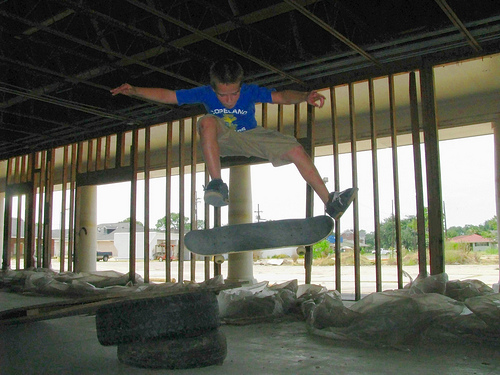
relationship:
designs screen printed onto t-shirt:
[217, 111, 251, 133] [171, 80, 278, 132]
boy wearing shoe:
[106, 57, 358, 223] [202, 180, 228, 205]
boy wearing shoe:
[106, 57, 358, 223] [325, 186, 357, 217]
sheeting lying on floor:
[5, 265, 499, 357] [1, 286, 497, 373]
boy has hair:
[106, 57, 358, 223] [202, 52, 274, 99]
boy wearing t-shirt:
[106, 57, 358, 223] [173, 81, 273, 133]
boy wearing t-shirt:
[106, 57, 358, 223] [166, 77, 273, 132]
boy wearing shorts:
[106, 57, 358, 223] [194, 114, 300, 166]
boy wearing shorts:
[106, 57, 358, 223] [197, 113, 302, 172]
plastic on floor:
[235, 274, 498, 354] [17, 279, 454, 374]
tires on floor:
[114, 329, 232, 372] [1, 286, 497, 373]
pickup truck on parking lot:
[92, 249, 114, 264] [11, 257, 498, 307]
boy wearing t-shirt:
[106, 57, 358, 223] [173, 81, 277, 128]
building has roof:
[443, 228, 498, 255] [442, 215, 498, 265]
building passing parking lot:
[443, 228, 498, 255] [4, 253, 497, 295]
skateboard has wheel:
[183, 215, 336, 263] [212, 252, 224, 263]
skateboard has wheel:
[183, 215, 336, 263] [295, 247, 306, 256]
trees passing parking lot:
[372, 207, 444, 257] [5, 255, 499, 300]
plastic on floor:
[218, 270, 498, 355] [1, 286, 497, 373]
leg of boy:
[198, 114, 225, 207] [106, 57, 358, 223]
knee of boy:
[195, 115, 215, 137] [106, 57, 358, 223]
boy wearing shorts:
[106, 57, 358, 223] [187, 107, 292, 153]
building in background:
[443, 228, 498, 255] [3, 193, 498, 268]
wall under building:
[384, 74, 404, 297] [2, 5, 500, 304]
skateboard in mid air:
[183, 215, 336, 263] [133, 174, 372, 274]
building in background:
[443, 228, 498, 255] [57, 70, 473, 303]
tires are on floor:
[99, 301, 232, 372] [37, 330, 95, 355]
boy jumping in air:
[106, 57, 358, 223] [450, 151, 483, 189]